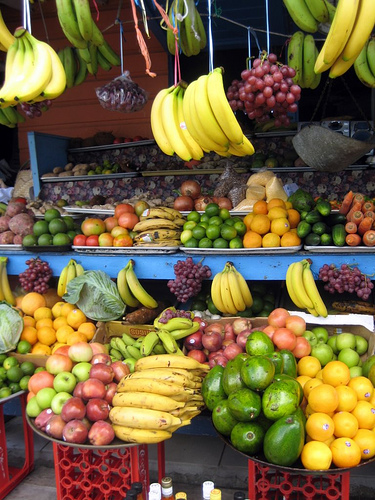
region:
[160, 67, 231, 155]
Bananas hanging above fruit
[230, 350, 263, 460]
Green fruit next to oranges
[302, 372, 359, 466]
Oranges next to green fruit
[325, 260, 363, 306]
Purple grapes next to bananas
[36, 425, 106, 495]
Fruit on red crate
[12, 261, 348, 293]
Grapes and bananas hanging from blue wood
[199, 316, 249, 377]
Apples in front of some bananas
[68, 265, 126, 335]
Green leafy vegetable in between bananas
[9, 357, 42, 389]
Limes under oranges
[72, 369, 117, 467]
Apples near bananas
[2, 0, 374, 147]
bunches of bananas hanging from string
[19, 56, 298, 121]
bags of grapes hanging from string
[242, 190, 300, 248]
bunch of lemons sitting on tray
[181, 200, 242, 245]
bunches of limes sitting on tray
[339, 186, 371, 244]
bunches of carrots on tray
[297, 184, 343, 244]
bunches of cucumber on tray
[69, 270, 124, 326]
head of cabbage sitting on box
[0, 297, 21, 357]
head of cabbage sitting on box of lemons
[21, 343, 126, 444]
apples sitting on round tray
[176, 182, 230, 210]
bunch of onions sitting on tray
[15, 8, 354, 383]
fruits and vegetables on display.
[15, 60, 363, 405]
large variety of fruits and vegetables on display.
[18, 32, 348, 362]
delicious fruits and vegetables on display.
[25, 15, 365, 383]
wide variety of fruits and vegetables on display.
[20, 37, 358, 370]
some ripe fruits and vegetables on display.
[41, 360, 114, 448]
delicious assortment of apples.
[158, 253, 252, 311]
some tasty grapes and bananas together.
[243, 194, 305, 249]
some sweet oranges on display.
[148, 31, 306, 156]
Some lovely grapes and bananas hanging on display.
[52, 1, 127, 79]
some pretty plantains available.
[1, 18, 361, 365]
wide variety of fruits and vegetables.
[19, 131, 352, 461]
great variety of fruits and vegetables.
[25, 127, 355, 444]
delicious variety of fruits and vegetables.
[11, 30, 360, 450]
beautiful collection of fruits and vegetables.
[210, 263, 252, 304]
a beautiful collection of bananas.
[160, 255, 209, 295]
a beautiful collection of grapes.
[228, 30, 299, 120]
a nice group of grapes hanging.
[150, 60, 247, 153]
a nice group of bananas hanging.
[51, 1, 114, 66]
a nice group of plantains hanging.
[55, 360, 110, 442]
lovely assortment of apples.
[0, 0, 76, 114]
Handle of bananas hang from the ceiling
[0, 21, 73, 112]
Handle of bananas are yellow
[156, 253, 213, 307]
Grapes next to bananas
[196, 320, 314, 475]
Avocado over a black container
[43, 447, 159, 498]
Red plastic box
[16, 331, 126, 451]
Apples are red and green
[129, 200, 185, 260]
Plantains are rip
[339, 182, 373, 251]
Carrots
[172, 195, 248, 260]
Limas are green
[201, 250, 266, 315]
Handle of bananas hangs from table